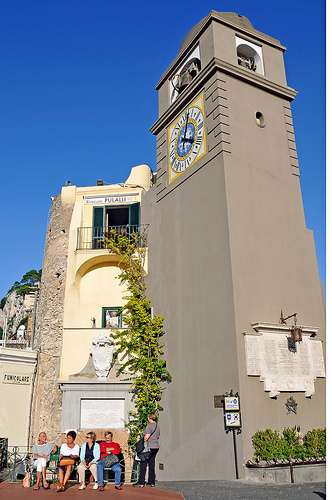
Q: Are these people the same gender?
A: No, they are both male and female.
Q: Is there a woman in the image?
A: Yes, there is a woman.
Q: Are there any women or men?
A: Yes, there is a woman.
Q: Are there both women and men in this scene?
A: Yes, there are both a woman and a man.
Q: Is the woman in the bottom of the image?
A: Yes, the woman is in the bottom of the image.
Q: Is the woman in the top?
A: No, the woman is in the bottom of the image.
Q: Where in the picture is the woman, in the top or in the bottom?
A: The woman is in the bottom of the image.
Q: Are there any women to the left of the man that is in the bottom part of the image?
A: Yes, there is a woman to the left of the man.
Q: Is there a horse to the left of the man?
A: No, there is a woman to the left of the man.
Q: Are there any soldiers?
A: No, there are no soldiers.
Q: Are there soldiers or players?
A: No, there are no soldiers or players.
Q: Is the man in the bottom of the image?
A: Yes, the man is in the bottom of the image.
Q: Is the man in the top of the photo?
A: No, the man is in the bottom of the image.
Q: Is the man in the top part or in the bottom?
A: The man is in the bottom of the image.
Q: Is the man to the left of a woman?
A: Yes, the man is to the left of a woman.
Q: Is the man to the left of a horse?
A: No, the man is to the left of a woman.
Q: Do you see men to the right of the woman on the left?
A: Yes, there is a man to the right of the woman.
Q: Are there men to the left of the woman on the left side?
A: No, the man is to the right of the woman.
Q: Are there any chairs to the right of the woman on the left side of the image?
A: No, there is a man to the right of the woman.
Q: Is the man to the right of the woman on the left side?
A: Yes, the man is to the right of the woman.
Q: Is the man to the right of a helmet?
A: No, the man is to the right of the woman.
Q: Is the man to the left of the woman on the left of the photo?
A: No, the man is to the right of the woman.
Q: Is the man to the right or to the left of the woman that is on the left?
A: The man is to the right of the woman.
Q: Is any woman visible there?
A: Yes, there is a woman.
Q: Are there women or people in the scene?
A: Yes, there is a woman.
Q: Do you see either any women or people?
A: Yes, there is a woman.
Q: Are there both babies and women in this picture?
A: No, there is a woman but no babies.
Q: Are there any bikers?
A: No, there are no bikers.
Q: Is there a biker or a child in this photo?
A: No, there are no bikers or children.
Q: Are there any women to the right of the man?
A: Yes, there is a woman to the right of the man.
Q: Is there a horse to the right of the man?
A: No, there is a woman to the right of the man.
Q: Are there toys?
A: No, there are no toys.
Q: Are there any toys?
A: No, there are no toys.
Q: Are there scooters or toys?
A: No, there are no toys or scooters.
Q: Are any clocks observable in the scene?
A: Yes, there is a clock.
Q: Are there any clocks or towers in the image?
A: Yes, there is a clock.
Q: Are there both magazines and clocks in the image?
A: No, there is a clock but no magazines.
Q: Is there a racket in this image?
A: No, there are no rackets.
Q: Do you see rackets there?
A: No, there are no rackets.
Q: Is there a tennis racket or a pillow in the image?
A: No, there are no rackets or pillows.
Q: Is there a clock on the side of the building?
A: Yes, there is a clock on the side of the building.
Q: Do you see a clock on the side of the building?
A: Yes, there is a clock on the side of the building.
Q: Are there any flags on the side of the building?
A: No, there is a clock on the side of the building.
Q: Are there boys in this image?
A: No, there are no boys.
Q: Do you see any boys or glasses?
A: No, there are no boys or glasses.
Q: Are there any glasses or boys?
A: No, there are no boys or glasses.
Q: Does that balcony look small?
A: Yes, the balcony is small.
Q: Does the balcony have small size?
A: Yes, the balcony is small.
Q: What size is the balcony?
A: The balcony is small.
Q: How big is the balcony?
A: The balcony is small.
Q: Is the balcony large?
A: No, the balcony is small.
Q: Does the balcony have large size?
A: No, the balcony is small.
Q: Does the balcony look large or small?
A: The balcony is small.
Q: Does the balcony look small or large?
A: The balcony is small.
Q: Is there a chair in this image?
A: No, there are no chairs.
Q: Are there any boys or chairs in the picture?
A: No, there are no chairs or boys.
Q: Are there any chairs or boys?
A: No, there are no chairs or boys.